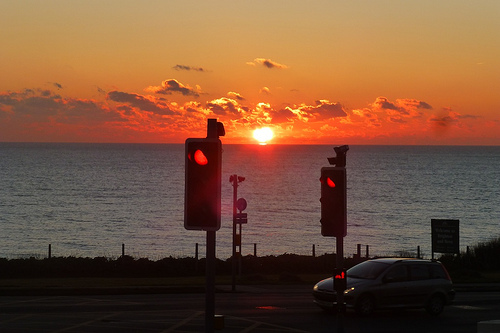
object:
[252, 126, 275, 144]
sun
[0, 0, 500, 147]
sky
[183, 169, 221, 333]
metal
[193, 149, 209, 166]
light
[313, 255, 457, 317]
car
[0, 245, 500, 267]
fence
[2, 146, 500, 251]
ocean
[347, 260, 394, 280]
windshield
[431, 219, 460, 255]
sign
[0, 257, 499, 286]
beach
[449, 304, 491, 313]
paint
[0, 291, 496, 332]
road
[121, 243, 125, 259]
post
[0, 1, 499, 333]
scene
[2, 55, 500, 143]
clouds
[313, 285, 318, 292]
light